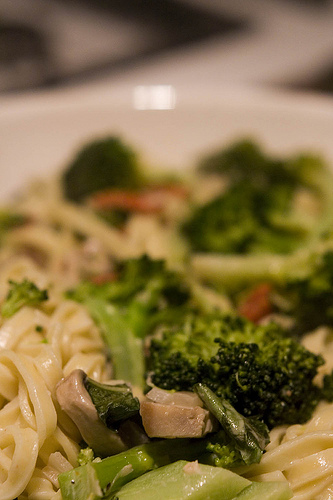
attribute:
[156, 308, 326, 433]
broccoli — very small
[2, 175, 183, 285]
noodles — blurry, background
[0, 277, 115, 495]
noodles — blurry, background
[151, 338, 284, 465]
vegetable — green 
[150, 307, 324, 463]
broccoli — large, piece, bush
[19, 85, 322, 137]
plate — red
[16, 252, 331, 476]
broccoli — piece, small, stem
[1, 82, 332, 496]
plate — food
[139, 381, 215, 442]
chicken — small, little, piece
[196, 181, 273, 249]
broccoli — blurry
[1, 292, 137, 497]
noodles — shiny, beige, cooked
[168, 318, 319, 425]
vegetable — green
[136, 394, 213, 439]
meat — brown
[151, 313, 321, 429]
broccoli — green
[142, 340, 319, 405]
vegetable — green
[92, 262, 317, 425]
vegetable — green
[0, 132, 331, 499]
broccoli — small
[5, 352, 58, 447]
noodle — white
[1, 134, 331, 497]
food — blurry, orange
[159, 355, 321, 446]
vegetable — red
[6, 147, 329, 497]
pasta — bunch, stuck together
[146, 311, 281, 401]
broccoli — piece, cooked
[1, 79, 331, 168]
plate — white